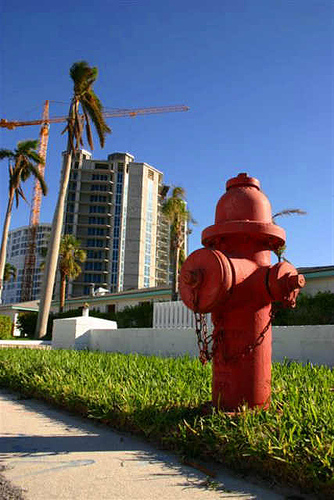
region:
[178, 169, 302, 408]
fire hydrant on the grass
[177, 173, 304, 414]
a red fire hydrant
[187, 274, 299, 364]
chains connected to the fire hydrant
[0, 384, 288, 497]
concrete path walk way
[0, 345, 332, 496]
green, lush grass lining the walk way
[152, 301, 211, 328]
part of white wooden fence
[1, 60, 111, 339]
long palm trees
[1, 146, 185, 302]
high rising buildings in the distance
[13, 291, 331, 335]
dark green shrubbery in front of the building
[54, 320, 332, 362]
low concrete white wall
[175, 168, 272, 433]
red hydrant on grass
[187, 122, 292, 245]
red cap on hydrant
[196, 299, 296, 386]
red chains on hydrant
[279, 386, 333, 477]
grass is light green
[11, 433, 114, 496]
sidewalk is light brown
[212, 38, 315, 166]
sky is light blue and cloudless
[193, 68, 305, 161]
sky has no clouds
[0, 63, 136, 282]
tall trees near hydrant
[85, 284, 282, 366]
white wall behind hydrant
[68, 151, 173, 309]
white and blue building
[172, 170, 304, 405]
a red fire hydrant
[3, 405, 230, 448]
a shadow from the fire hydrant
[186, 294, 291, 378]
a chain on the fire hydrant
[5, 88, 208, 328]
a crane by the building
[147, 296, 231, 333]
a white picket fence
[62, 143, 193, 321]
a tall white building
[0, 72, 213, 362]
several tall palm trees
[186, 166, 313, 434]
a fire hydrant in the grass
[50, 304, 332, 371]
a low white concrete wall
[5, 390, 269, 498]
sun shinning on the sidewalk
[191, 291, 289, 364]
Chains on a red fire hydrant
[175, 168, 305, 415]
Red fire hydrant in the grass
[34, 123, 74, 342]
Long trunk of a tree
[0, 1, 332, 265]
A bright blue sky without clouds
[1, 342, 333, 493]
A patch of bright green grass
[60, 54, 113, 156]
Top of a tree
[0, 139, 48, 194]
Leaves on a palm tree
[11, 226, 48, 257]
Windows on the side of a building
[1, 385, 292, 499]
Concrete footpath near grass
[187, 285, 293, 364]
Chains on a fire hydrant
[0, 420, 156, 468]
the shadow of the hydrant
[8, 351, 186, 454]
the tall green grass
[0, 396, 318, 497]
a concrete side walk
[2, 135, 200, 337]
a huge tall building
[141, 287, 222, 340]
a white object in front of wall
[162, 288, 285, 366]
a red chain on hydrant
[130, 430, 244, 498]
the shadow of the grass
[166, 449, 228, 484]
a rusty bolt on walk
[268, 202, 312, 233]
a feather on the hydrant